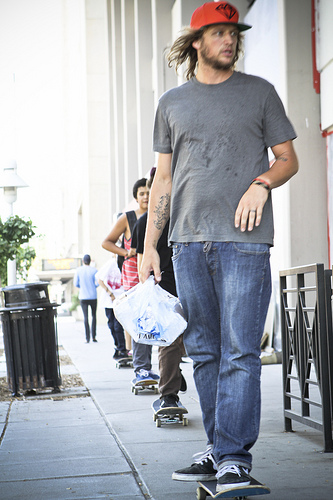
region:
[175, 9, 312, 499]
Man skateboarding down the sidewalk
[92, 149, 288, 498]
Line of men skateboarding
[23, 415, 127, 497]
Cracks in the sidewalk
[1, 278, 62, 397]
Black trashcan on side of road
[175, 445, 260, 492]
Black and white tennis shoes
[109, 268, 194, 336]
Man holding a plastic bag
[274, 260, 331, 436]
Metal gate is open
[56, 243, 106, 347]
Man walking away from group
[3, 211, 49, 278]
Tree growing beside sidewalk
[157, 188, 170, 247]
Tattoo on man's arm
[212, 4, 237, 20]
Black diamond drawing on hat.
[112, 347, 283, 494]
Four skateboards being rode on the sidewalk.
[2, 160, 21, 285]
White street light.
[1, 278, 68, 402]
Brown garbage can.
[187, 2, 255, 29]
Orange and black hat.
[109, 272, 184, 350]
Small white paper bag being held by man.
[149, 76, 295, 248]
Grey tshirt being worn by skateboarder.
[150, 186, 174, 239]
Tattoo on man's right forearm.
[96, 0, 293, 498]
Man in orange cap leading skateboarders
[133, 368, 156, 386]
Blue sneakers worn by skateboarder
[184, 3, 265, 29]
man wearing red hat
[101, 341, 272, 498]
four guys skateboarding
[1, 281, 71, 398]
black city trashcan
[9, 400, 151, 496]
concrete sidewalk in the city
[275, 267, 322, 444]
black iron small fence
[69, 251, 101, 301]
man wearing blue shirt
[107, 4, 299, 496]
man skateboarding wearing gray shirt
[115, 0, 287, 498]
man carrying a grocery bag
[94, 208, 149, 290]
boy with red striped shirt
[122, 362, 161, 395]
blue skateboarding shoes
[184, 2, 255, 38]
the mans hat is orange and black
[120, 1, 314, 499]
the man is riding a skateboard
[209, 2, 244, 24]
the hat has a black diamond on it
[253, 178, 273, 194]
he has 2 rubber bracelets on his wrist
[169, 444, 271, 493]
he is wearing vans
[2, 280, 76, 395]
the garbage can is on the edge of the sidewalk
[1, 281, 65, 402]
the trash can is black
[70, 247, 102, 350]
the person is walking down the street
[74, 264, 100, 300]
the person is waring a baby blue tee shirt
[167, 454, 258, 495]
his sneakers are black and white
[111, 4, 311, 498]
man wearing a red cap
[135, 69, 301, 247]
tee shirt is gray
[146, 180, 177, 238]
tattoo on arm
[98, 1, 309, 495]
man holding a bag on right hand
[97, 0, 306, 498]
man stand on a skateboard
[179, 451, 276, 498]
skateboard is black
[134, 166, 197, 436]
a person on a skateboard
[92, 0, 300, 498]
four persons on skateboards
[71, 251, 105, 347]
person walking down the street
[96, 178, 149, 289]
man wearing a black backpack